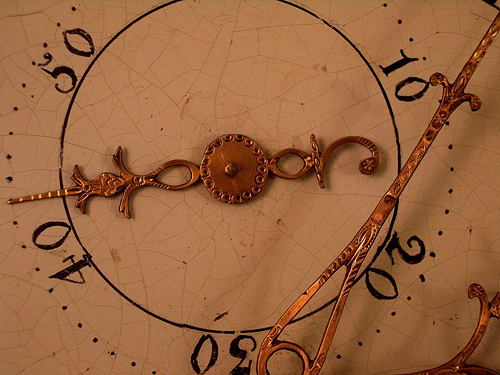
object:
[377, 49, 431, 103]
10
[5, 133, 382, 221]
dial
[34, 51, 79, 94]
number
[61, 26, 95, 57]
number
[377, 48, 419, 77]
number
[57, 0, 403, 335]
circle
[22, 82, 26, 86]
dot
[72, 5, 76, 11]
dot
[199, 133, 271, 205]
circle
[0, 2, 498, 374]
background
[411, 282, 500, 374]
decoration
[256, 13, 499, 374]
dial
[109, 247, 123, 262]
mark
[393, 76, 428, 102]
number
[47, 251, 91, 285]
number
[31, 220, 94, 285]
40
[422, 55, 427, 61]
dot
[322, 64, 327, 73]
speck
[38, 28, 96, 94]
50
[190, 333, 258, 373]
30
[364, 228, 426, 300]
20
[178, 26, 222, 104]
crack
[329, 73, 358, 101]
crack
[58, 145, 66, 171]
edge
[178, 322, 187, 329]
protuberance